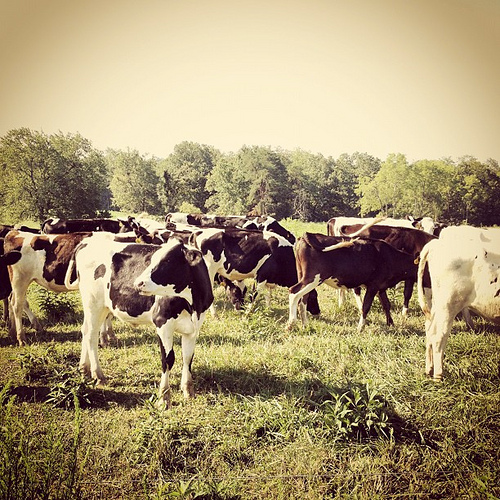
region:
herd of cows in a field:
[27, 204, 489, 414]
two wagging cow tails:
[318, 217, 386, 257]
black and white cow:
[68, 238, 217, 413]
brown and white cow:
[7, 224, 88, 298]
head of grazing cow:
[301, 291, 321, 324]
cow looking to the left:
[122, 226, 202, 311]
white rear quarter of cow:
[410, 230, 485, 332]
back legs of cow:
[273, 271, 316, 336]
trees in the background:
[263, 161, 376, 234]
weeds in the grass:
[321, 381, 406, 450]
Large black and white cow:
[62, 226, 232, 407]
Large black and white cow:
[410, 230, 499, 365]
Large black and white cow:
[276, 232, 430, 337]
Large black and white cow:
[191, 230, 322, 313]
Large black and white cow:
[2, 224, 111, 364]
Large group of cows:
[6, 199, 497, 429]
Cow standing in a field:
[63, 228, 220, 408]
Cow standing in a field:
[266, 229, 431, 341]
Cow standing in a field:
[188, 223, 313, 320]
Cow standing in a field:
[0, 222, 112, 362]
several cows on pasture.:
[50, 86, 476, 433]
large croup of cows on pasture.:
[3, 113, 480, 417]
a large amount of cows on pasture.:
[28, 66, 487, 426]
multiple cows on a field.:
[27, 111, 479, 430]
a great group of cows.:
[60, 78, 480, 430]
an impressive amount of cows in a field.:
[27, 83, 477, 434]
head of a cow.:
[132, 233, 202, 315]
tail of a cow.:
[407, 243, 437, 318]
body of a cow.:
[320, 232, 385, 304]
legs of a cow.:
[60, 303, 213, 408]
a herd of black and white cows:
[5, 197, 497, 409]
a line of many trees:
[0, 116, 495, 233]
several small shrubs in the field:
[3, 342, 410, 492]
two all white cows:
[400, 224, 497, 394]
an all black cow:
[336, 220, 458, 289]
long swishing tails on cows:
[304, 209, 393, 276]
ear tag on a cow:
[408, 247, 429, 270]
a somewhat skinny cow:
[1, 219, 156, 369]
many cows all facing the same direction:
[3, 181, 498, 423]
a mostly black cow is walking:
[267, 230, 455, 336]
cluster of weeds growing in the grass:
[324, 378, 400, 446]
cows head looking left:
[140, 242, 207, 314]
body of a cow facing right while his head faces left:
[63, 239, 217, 409]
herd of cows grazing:
[6, 199, 488, 413]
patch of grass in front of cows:
[3, 348, 495, 495]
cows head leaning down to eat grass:
[291, 288, 326, 329]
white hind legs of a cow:
[413, 241, 496, 398]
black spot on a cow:
[86, 260, 112, 285]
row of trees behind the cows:
[2, 122, 499, 229]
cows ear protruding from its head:
[174, 246, 214, 280]